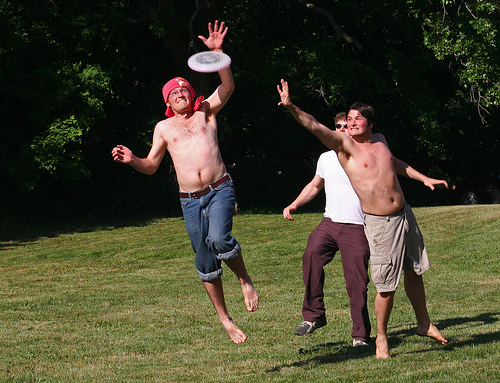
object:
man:
[110, 19, 259, 345]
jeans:
[179, 173, 241, 281]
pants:
[302, 216, 370, 342]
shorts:
[360, 200, 430, 292]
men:
[112, 19, 448, 360]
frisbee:
[188, 51, 231, 72]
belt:
[179, 175, 229, 200]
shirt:
[315, 150, 364, 225]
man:
[276, 79, 448, 358]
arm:
[288, 103, 342, 150]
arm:
[203, 50, 234, 114]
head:
[162, 77, 194, 115]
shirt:
[162, 77, 202, 117]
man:
[283, 112, 370, 347]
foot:
[293, 316, 327, 336]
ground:
[0, 0, 500, 383]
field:
[0, 204, 500, 382]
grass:
[0, 204, 500, 383]